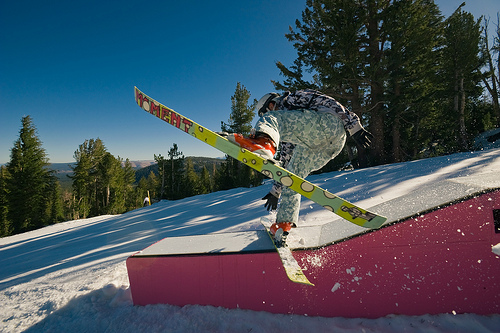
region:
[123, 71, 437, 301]
man doing ski trick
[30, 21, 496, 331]
a snowy landscape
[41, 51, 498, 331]
a skier performing tricks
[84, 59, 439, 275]
a person wears brightly colored skis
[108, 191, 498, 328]
the trick platform has a pink side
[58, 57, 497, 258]
the skier is wearing orange boots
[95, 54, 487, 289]
the skier is wearing camouflage clothing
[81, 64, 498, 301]
the skier is wearing a helmet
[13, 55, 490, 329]
snow is on the ground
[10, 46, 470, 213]
pine trees are on the mountain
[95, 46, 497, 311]
the skier is lifting one leg in the air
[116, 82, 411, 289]
the design on the skis is funny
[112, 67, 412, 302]
the skier looks like he is about to fall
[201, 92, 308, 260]
the ski boots are bright orange in color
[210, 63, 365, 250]
the skier has on camoflage pants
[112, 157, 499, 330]
the platform is pink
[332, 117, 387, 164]
the skier is wearing gloves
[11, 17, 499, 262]
many evergreen trees line the hill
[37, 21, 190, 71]
the sky is crystal clear blue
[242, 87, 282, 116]
the skier is wearing a helmet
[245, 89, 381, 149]
the ski jacket looks funny with those pants.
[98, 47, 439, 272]
the skier appears to be having trouble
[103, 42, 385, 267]
the skis are very colorful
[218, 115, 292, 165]
the person is wearing orange ski boots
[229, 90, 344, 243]
the skier's pants are camo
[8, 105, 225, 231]
the evergreen trees are plentiful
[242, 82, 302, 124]
the skier is wearing a helmet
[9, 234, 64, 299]
the snow appears to be rather deep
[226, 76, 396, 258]
the skier is wearing gloves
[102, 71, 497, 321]
the skier appears to be about to fall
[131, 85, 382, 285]
Man wearing snow skis.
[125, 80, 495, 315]
Man performing a snow ski stunt.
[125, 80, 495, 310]
Man on a board performing a ski trick.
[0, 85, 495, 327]
Man skiing on a snowy mountain.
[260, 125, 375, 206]
Black gloves on man's hands.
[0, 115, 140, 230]
Green trees on the resort's ground.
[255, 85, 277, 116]
Helmet on skier's head.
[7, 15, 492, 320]
Skier skiing at a resort.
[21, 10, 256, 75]
Clear blue ski above the trees.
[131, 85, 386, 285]
Snow skis on the skier's feet.